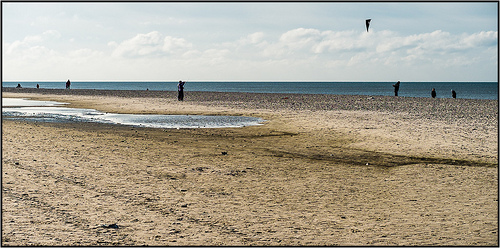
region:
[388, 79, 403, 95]
person on a beach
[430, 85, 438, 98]
person on a beach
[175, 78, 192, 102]
person on a beach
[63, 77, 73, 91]
person on a beach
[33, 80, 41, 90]
person on a beach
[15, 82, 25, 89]
person on a beach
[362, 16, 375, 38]
kite in the air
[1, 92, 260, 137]
puddle of water on the beach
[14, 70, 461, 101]
people standing on the beach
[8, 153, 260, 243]
tire tracks on the sand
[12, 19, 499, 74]
clouds in the light blue sky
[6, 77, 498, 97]
calm ocean waters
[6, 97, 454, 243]
footprints in the sand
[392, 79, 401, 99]
person flying the kite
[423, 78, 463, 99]
people close to the water's edge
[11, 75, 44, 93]
people in the far distance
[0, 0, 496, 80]
A blue sky with white clouds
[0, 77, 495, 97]
A strip of blue water.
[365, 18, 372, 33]
A small black kite.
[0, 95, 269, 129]
Large silver puddles in the sand.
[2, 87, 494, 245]
A large sandy beach with people standing on it.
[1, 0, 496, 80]
A light blue sky.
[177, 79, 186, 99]
Two people standing in the middle of the beach.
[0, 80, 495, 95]
A blue strip of water past the beach.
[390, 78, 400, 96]
A person leaning back controlling a kite.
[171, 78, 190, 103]
a man standing on the beach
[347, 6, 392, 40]
a kite soaring across the sky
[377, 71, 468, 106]
bystanders on the beach on a sunny day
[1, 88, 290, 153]
puddles on a beach shore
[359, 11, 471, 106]
some kite flyers gather on the shore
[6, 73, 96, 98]
people walk across the sand by the ocean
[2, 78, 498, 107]
a shoreline on a clear blue day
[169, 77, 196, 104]
a man on the beach watches the water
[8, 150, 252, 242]
tire tracks running through some sand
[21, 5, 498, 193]
the kites are flying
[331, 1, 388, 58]
the kite is in the wind